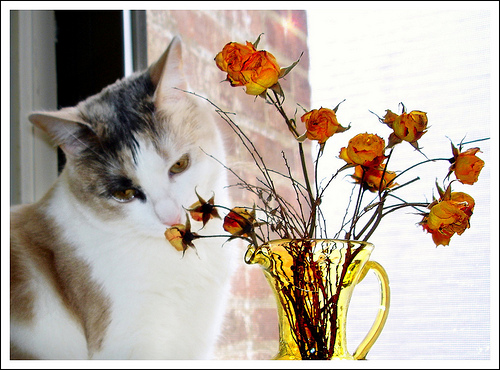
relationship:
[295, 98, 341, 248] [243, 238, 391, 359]
rose in pitcher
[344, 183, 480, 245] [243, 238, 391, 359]
rose in pitcher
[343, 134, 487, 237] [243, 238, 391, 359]
rose in pitcher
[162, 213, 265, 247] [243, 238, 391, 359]
rose in pitcher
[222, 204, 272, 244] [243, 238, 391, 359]
rose in pitcher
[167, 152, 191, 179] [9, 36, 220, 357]
eyes on cat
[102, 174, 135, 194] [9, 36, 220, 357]
eye on cat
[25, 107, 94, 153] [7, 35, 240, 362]
ear on cat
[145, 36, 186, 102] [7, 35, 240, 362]
ear on cat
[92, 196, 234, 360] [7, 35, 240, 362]
chest on cat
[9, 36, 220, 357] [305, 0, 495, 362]
cat in window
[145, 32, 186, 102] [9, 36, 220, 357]
ear on cat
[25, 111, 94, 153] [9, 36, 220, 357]
ear on cat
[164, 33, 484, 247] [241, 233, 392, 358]
roses in vase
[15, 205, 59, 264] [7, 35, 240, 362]
brown on cat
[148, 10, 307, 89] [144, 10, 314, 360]
bricks on wall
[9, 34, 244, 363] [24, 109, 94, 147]
fur in ear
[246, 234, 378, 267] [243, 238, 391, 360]
lid on pitcher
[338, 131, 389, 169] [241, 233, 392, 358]
flower in vase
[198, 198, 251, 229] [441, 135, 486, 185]
stem on rose